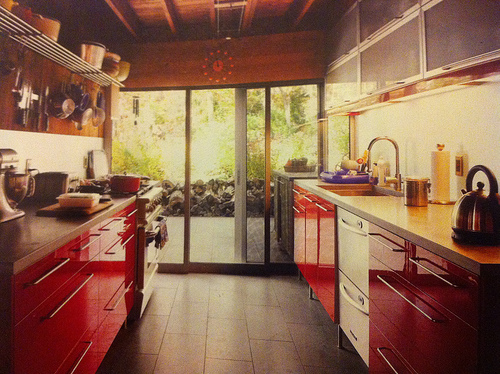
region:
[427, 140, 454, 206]
a roll of paper towels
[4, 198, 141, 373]
red drawers with handles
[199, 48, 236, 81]
an orange clock on the wall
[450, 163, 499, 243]
a silver kettle with a black handle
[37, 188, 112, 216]
a cutting board with a dish on it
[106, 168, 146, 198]
a red pot on a stove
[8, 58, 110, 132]
pots hanging on the wall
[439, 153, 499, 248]
a teakettle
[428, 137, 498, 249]
A teakettle and a roll of paper towels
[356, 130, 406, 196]
a kitchen faucet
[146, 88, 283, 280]
a glass sliding door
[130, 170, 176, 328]
an oven door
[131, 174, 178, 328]
an oven door with a towel on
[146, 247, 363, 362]
the kitchen floor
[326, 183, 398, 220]
a kitchen sink and countertop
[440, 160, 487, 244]
chrome and black tea kettle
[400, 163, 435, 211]
chrome canister on counter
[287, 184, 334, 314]
red cabinet doors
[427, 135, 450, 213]
paper towel holder with paper towels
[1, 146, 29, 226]
large stand alone mixer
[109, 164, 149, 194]
red pot on the stove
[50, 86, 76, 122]
pot hanging on the wall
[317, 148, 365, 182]
purple dish holder on counter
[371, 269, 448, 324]
long chrome handle on drawer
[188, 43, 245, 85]
clock above the door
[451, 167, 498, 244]
a stainless steel water kettle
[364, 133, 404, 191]
a stainless steel faucet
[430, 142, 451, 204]
white paper towels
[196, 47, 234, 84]
a clock on the wall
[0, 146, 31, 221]
a silver mixer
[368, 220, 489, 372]
red colored kitchen cabinets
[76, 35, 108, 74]
a stainless steel cooking pot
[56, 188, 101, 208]
a white colored container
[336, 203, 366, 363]
a white colored dishwater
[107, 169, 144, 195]
a red stock pot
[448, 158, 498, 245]
stainless steel kettle sitting on counter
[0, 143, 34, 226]
kitchen aid stand mixer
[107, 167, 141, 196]
red pot on stove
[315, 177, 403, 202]
single large sink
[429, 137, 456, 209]
roll of paper towels on counter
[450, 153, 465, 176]
outlet on kitchen wall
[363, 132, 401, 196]
chrome sink curved facet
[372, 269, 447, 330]
long handle on drawer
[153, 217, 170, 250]
towel hanging from door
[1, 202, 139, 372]
Shiny red cabinets in kitchen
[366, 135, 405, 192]
Kitchen sink faucet with high arch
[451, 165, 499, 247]
Black and silver tea kettle sitting on countertop